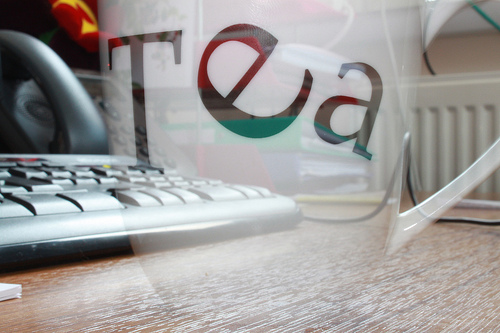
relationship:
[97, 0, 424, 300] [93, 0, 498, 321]
black tea written on cup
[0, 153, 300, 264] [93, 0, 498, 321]
computer keyboard behind cup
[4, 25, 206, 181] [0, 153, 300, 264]
phone behind computer keyboard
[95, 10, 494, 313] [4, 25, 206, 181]
glare on phone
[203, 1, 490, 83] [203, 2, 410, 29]
moulding on window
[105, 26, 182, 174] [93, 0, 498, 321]
letter on cup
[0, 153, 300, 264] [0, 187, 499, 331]
computer keyboard on desk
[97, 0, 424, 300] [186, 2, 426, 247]
black tea on mug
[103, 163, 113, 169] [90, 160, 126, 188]
dial pad on key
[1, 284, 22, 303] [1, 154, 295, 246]
papers front left of keyboard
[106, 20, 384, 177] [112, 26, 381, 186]
word spelling tea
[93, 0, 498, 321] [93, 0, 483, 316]
cup seen in ghost image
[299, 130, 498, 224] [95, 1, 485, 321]
wire showing through image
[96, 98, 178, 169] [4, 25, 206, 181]
dial pad built into phone